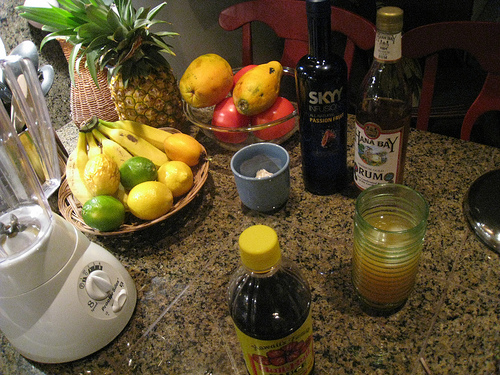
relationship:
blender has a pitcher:
[2, 206, 139, 371] [0, 43, 64, 277]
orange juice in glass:
[354, 216, 422, 309] [355, 181, 428, 318]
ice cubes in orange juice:
[367, 224, 413, 270] [354, 216, 422, 309]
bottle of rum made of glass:
[353, 6, 411, 203] [352, 56, 414, 134]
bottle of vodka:
[296, 0, 351, 199] [309, 89, 347, 124]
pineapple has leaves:
[110, 67, 186, 135] [83, 7, 179, 85]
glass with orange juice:
[355, 181, 428, 318] [354, 216, 422, 309]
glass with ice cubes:
[355, 181, 428, 318] [367, 224, 413, 270]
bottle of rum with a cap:
[353, 6, 411, 203] [375, 7, 406, 33]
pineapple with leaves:
[110, 67, 186, 135] [83, 7, 179, 85]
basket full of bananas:
[56, 156, 210, 237] [66, 116, 180, 206]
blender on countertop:
[2, 206, 139, 371] [2, 3, 498, 372]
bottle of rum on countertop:
[353, 6, 411, 203] [2, 3, 498, 372]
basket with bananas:
[56, 156, 210, 237] [66, 116, 180, 206]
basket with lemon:
[56, 156, 210, 237] [126, 180, 176, 221]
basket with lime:
[56, 156, 210, 237] [82, 196, 126, 233]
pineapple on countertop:
[110, 67, 186, 135] [2, 3, 498, 372]